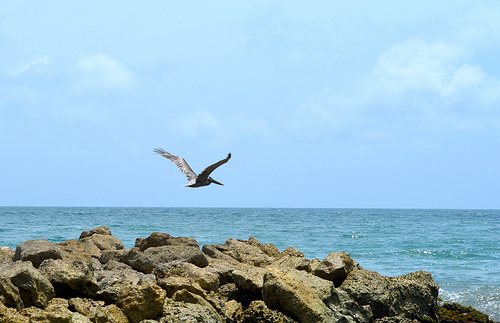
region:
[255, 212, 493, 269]
THE OCEAN IS CALM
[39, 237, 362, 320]
THE ROCKS ARE JAGGED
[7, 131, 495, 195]
THE SKY IS BLUE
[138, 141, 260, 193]
THE PELICAN IS FLYING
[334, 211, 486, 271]
THE WATER IS GREEN BLUE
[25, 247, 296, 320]
THE ROCKS ARE LIGHT BROWN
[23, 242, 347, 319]
THE ROCKS APPEAR TO BE DRY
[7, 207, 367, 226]
THE WATER IS WET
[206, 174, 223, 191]
THE BIRD HAS A LARGE BEAK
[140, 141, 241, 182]
THE WING SPAN IS WIDE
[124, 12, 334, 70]
this is the sky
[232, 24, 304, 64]
the sky is blue in color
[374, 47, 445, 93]
these are the clouds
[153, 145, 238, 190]
this is a bird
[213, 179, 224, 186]
this is the beak of the bird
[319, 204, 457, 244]
this is a water body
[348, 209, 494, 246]
the water is calm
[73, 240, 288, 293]
these are the rocks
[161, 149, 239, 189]
the bird is flying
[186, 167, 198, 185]
the bird is black in color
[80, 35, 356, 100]
Sky is blue color.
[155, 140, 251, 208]
Bird is flying in air.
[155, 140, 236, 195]
Bird is grey color.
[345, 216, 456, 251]
Water is blue color.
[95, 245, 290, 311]
Rocks are brown color.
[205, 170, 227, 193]
Bird has a long beak.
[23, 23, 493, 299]
Day time picture.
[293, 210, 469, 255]
Water is calm and quiet.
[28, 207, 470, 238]
Water is seen behind the rocks.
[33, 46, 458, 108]
Few clouds in sky.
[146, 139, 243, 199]
Seabird flying over stones.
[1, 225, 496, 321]
Stones near ocean.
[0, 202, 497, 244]
Water is blue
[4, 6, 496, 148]
Sky is cloudy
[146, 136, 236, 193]
Pelican has extended wings.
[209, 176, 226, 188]
Pelican has big peak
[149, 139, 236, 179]
Wings are large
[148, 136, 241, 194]
Pelican fly to the right.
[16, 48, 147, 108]
Cloud formed in the sky.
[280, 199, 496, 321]
Water of ocean is wave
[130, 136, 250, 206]
A lone bird flies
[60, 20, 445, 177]
A beautiful blue sky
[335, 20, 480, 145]
A light fluffy cloud hides in the sky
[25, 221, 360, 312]
A rock pile at the waters edge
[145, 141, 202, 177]
Light shines on the bird's wing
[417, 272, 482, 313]
White tops on the water as it hits the shore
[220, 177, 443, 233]
The water meets the horizon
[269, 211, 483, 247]
Glistening blue water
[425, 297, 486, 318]
Green at the water's edge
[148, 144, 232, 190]
A long wing span